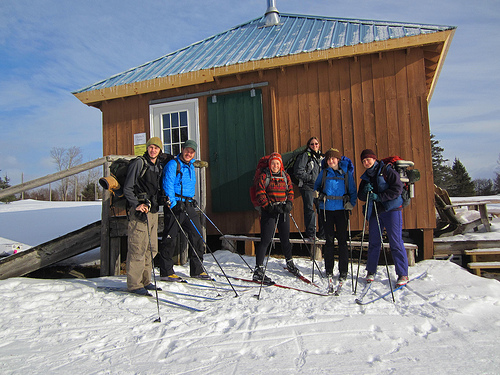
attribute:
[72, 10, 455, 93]
roof — metal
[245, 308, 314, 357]
floor — white 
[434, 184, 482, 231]
chair — wooden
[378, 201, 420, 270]
pants — purple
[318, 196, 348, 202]
strap — gray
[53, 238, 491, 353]
snow — white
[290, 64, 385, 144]
shed — wood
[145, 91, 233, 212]
door — white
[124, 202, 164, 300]
pants — tan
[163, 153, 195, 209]
jacket — blue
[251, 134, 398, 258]
women — four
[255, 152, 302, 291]
skier — woman/female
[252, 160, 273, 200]
backpack — red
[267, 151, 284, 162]
hat — red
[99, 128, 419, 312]
people — five people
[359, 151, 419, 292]
woman — blue-wearing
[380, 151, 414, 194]
backpack — red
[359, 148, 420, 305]
skier — blue-wearing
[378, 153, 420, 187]
backpack — red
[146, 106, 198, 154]
door — white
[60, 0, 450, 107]
roof — tin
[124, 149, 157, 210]
jacket — black, colored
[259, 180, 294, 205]
jacket — colored, red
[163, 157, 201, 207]
jacket — blue, colored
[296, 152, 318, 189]
jacket — grey, colored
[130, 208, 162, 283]
pants — grey, colored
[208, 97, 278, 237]
door — colored, green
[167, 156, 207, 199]
jacket — blue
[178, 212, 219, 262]
pants — black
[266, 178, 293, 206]
sweater — red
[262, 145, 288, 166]
hat — red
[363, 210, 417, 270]
pants — purple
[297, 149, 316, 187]
jacket — gray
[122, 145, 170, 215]
sweater — white, gray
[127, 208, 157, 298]
pants — white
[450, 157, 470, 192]
leaves — green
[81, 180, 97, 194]
leaves — green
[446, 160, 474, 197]
leaves — green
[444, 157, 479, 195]
leaves — green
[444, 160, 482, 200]
leaves — green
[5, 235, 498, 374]
field — snowy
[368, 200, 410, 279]
pants — purple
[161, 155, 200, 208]
jacket — blue